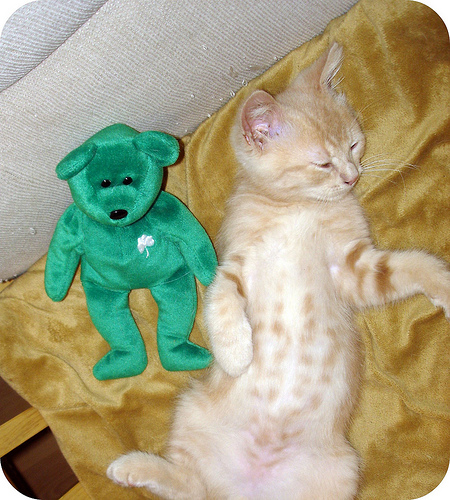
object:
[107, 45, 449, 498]
kitten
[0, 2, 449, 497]
couch